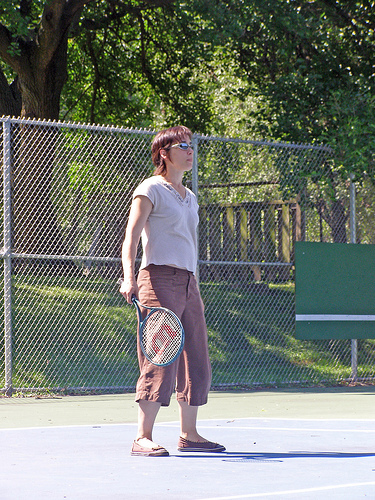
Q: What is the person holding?
A: Tennis racket.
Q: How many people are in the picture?
A: One.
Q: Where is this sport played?
A: Tennis court.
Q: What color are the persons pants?
A: Brown.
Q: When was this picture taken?
A: Day time.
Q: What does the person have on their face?
A: Sunglasses.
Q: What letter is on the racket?
A: W.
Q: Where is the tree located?
A: Other side of fence.